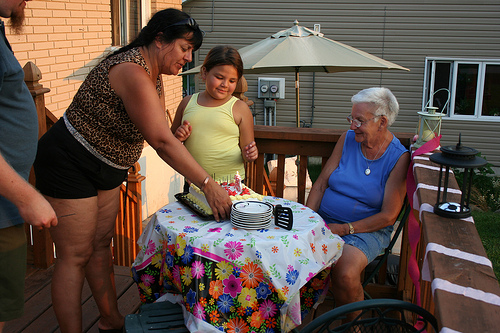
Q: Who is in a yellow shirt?
A: Young girl.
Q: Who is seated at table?
A: Old woman.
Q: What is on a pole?
A: Umbrella.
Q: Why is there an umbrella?
A: Shade.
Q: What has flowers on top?
A: Table cloth.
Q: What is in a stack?
A: Plates.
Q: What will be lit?
A: Candles on cake.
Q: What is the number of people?
A: 4.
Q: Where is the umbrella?
A: At the bottom of the steps.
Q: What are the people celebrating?
A: A birthday.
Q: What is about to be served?
A: Cake.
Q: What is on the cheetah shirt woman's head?
A: Sunglasses.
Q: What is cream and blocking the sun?
A: Umbrella.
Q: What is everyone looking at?
A: Cake.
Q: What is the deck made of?
A: Wood.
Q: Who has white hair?
A: The elderly woman.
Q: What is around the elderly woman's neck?
A: Necklace.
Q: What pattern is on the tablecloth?
A: Floral.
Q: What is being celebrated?
A: Birthday.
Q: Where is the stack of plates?
A: On the table.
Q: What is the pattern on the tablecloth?
A: Flowers.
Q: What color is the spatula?
A: Black.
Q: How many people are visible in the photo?
A: Four.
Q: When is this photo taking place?
A: Daytime.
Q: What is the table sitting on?
A: Wooden deck.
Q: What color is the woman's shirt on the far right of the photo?
A: Blue.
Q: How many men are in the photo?
A: One.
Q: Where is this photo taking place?
A: On a deck.